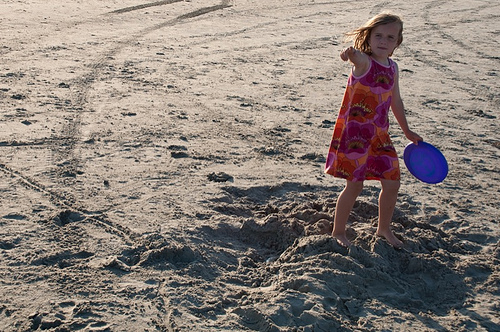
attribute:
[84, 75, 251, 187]
sand — large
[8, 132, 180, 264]
track — small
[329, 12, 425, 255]
girl — little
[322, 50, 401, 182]
dress — orange, pink, red, colorful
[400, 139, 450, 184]
frisbee — blue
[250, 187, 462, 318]
sand — gray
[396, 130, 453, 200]
disk — medium blue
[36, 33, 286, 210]
sand — Large 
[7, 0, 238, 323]
tracks — large, vehicle tracks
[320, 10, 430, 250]
girl pointing — young, blonde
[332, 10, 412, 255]
girl — pointing 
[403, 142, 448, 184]
frisbee — purple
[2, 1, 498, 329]
sand — large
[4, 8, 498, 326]
ground — covered